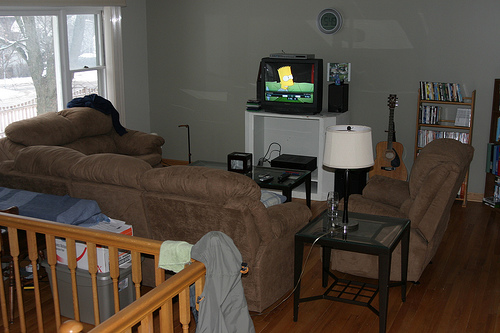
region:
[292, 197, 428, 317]
a glass topped side table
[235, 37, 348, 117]
a small black tv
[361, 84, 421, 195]
a wood gibson guitar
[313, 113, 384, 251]
a lamp with a white shade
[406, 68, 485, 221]
a wooden bookshelf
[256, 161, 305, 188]
a remote control on table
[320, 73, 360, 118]
a large black speaker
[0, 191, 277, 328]
a large wooden crib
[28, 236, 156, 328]
a grey plastic container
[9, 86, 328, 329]
a large brown sectional couch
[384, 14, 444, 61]
part of a wall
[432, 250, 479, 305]
part of the floor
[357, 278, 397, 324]
stand of a stool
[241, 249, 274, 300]
edge of a sofa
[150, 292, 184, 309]
edge of a wood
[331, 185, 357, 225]
stand of a lamp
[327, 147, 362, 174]
part of a lamp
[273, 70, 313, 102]
part of a screen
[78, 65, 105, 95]
part of a window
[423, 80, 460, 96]
part of some books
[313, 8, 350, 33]
Silver circular clock hanging on the wall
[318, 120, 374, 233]
Black lamp with a white shade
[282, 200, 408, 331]
Black glass top table on the floor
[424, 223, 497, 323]
Wooden flooring in a family room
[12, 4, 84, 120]
Tree with no leaves sitting in the snow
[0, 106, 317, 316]
Large brown sectional couch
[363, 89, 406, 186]
Acoustic guitar leaning against the wall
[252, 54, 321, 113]
Black TV with the Simpsons displayed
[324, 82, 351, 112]
Black speaker sitting on a TV stand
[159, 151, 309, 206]
Black table in front of a TV with remotes sitting on it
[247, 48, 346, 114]
Television set on tv stand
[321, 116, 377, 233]
lamp on glass table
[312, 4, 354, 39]
digital clock on wall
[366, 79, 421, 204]
guitar leaning against wall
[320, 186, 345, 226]
drinking glass on table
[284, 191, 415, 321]
glass table between chairs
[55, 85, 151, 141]
clothes on edge of couch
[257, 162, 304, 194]
remotes on glass table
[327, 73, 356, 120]
speaker next to television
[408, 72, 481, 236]
DVD stand next to wall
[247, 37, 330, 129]
black tv sitting on stand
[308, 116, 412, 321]
black lamp with white shade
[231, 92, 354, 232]
white entertainment stand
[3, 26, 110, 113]
snow outside window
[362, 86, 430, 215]
guitar sitting against wall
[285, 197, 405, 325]
black and glass end table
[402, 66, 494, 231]
wooden rack holding movies and games sitting against wall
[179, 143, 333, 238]
black and glasses coffee table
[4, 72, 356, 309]
large brown sofa in middle of room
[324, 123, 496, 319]
large brown recliner facing window